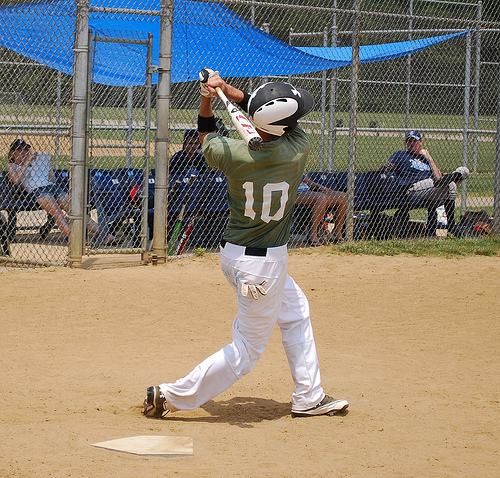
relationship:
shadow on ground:
[160, 393, 290, 430] [216, 425, 469, 475]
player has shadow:
[139, 65, 348, 419] [160, 393, 290, 430]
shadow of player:
[160, 393, 290, 430] [139, 65, 348, 419]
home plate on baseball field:
[92, 432, 194, 454] [2, 234, 499, 475]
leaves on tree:
[26, 75, 58, 105] [25, 77, 49, 98]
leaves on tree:
[439, 49, 458, 69] [434, 52, 454, 79]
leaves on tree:
[435, 61, 447, 78] [445, 49, 461, 76]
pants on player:
[174, 236, 323, 407] [168, 54, 324, 410]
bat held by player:
[226, 86, 262, 148] [213, 85, 265, 169]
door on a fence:
[85, 24, 155, 265] [17, 84, 61, 126]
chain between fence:
[112, 73, 142, 117] [71, 21, 163, 263]